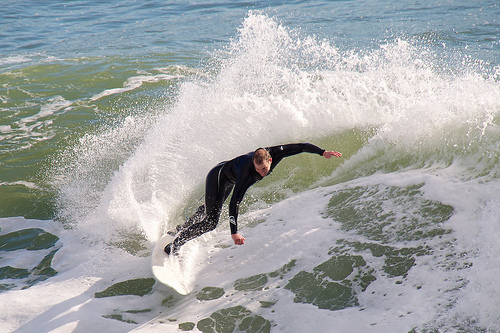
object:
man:
[164, 141, 342, 257]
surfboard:
[148, 231, 198, 298]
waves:
[2, 49, 210, 206]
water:
[0, 0, 498, 332]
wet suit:
[166, 144, 325, 248]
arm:
[278, 142, 323, 156]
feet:
[164, 244, 180, 255]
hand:
[231, 233, 248, 245]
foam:
[1, 165, 499, 327]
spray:
[30, 9, 500, 241]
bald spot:
[255, 148, 269, 159]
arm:
[230, 178, 248, 234]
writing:
[229, 217, 237, 224]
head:
[254, 146, 273, 178]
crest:
[6, 54, 180, 84]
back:
[228, 160, 250, 171]